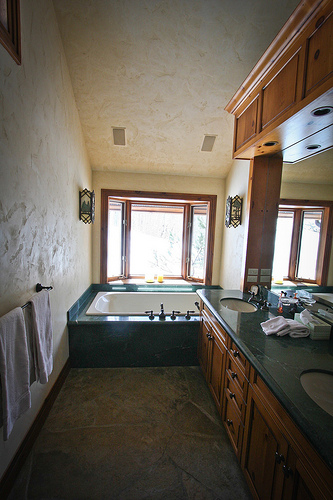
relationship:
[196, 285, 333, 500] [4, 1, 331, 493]
center inside bathroom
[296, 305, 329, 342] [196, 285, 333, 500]
towel on top of center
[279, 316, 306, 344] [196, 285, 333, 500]
towel on top of center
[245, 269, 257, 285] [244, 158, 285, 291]
electrical outlet on wall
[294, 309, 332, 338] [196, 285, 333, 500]
box on center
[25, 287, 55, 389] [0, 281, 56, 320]
towel hanging on rod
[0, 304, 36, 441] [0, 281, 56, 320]
towel hanging on rod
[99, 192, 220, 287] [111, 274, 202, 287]
window has sill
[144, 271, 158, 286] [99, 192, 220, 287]
candle in top of window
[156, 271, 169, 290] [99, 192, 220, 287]
candle in top of window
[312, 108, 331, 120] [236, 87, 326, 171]
vent in ceiling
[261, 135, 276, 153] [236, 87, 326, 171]
vent in ceiling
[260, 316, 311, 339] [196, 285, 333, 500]
towel on top of center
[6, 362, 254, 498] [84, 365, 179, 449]
floor has a part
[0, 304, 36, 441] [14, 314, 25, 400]
towel has part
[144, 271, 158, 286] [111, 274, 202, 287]
candle on top of sill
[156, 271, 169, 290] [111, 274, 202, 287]
candle on top of sill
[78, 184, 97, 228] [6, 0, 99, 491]
light on wall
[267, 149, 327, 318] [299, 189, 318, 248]
mirror has a part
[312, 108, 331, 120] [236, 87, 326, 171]
vent on ceiling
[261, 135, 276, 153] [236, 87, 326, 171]
vent on ceiling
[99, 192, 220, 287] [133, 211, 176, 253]
window has a part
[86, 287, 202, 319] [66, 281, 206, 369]
bath tub surrounded by marble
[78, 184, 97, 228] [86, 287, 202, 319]
light above bath tub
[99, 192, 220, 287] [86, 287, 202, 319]
window beside bath tub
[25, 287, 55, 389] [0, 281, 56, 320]
towel hanging from rack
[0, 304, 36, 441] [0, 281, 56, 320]
towel hanging from rack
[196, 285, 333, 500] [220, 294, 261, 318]
center has sink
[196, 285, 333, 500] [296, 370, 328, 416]
center has sink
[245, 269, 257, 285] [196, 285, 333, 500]
electrical outlet above center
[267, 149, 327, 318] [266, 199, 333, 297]
mirror reflecting window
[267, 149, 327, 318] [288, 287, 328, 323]
mirror reflecting bath tub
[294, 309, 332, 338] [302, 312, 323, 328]
box has facial tissues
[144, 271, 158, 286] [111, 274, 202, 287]
candle on sill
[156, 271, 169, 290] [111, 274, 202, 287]
candle on sill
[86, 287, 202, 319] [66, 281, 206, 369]
bath tub made of marble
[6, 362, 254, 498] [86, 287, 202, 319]
floor match bath tub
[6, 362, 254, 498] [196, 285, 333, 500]
floor match center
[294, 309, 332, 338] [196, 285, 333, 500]
box above center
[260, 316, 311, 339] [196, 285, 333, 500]
towel laying on center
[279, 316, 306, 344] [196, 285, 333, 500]
towel laying on center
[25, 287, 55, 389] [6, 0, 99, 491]
towel hanging on wall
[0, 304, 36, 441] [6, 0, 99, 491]
towel hanging on wall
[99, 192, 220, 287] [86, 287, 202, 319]
window next to bath tub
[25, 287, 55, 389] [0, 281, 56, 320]
towel on rack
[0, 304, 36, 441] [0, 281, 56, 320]
towel on rack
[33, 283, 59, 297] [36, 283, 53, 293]
fixture are for fixture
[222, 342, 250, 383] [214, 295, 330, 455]
drawer in center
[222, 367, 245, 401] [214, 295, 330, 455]
drawer in center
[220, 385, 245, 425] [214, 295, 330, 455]
drawer in center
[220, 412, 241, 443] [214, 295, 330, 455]
drawer in center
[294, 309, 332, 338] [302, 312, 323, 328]
box fulled with facial tissues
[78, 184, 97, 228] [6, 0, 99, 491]
light hanging on wall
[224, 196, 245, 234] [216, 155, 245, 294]
light hanging on wall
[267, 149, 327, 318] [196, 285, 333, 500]
mirror above center